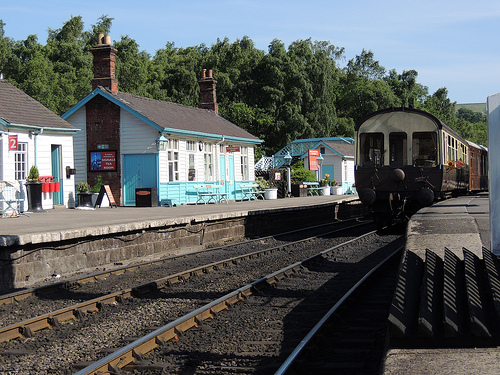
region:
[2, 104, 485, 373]
A train on train tracks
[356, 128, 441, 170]
Front windows of the train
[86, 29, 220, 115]
Two chimneys on top of a building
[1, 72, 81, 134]
The roof of a building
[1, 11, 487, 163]
Green leaves on many trees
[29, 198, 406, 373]
Shadows on the train tracks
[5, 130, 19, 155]
Number 2 on a sign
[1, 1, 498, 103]
The sky is blue and clear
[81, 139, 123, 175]
Signs on the side of a building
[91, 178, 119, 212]
A sign on the ground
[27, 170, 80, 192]
pink buckets at front of house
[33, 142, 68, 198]
blue door on the white house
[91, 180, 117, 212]
small red and white sign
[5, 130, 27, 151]
small red and white sign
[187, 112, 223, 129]
gray sloped roof on building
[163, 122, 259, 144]
blue edge on roof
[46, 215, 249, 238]
long black cable under platform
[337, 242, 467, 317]
reflection on the tracks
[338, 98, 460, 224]
large train on the track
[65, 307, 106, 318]
black soot on the tracks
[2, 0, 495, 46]
blue sky over a train station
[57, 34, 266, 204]
white and blue train station with two chimneys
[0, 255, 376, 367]
two train tracks at a station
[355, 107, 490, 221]
white and black train at a station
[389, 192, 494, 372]
gray and black platform area with raised ridges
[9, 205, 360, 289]
gray cinder block wall at a train station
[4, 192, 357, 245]
gray cement platform at a train station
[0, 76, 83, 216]
white and blue building with a black roof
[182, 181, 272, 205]
blue benches at a train station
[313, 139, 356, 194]
small blue and white building at a train station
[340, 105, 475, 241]
Train on the tracks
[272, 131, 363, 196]
Building in the background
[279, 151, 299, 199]
Lamp post on platform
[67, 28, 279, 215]
Building near the platform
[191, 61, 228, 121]
Chimney on top of building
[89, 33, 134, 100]
Chimney on top of building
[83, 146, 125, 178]
Sign on side of building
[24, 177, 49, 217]
Black pot on platform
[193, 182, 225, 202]
Chairs near building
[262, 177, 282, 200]
Flower pot on platform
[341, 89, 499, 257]
Brown and tan train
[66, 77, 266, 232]
Blue and white building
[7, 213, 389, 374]
Brown train tracks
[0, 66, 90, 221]
Small white building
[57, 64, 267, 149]
Black tile roof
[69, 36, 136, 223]
Brown brick chimney on white building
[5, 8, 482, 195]
Group of tall trees in the distance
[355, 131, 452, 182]
Three windows on the front of the train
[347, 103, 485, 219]
One large train car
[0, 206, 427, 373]
Black and grey gravel